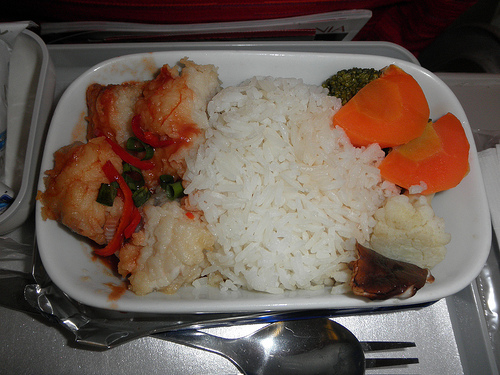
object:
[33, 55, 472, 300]
meal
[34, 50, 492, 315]
plate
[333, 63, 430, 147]
food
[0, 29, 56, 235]
tray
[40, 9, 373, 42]
magazine